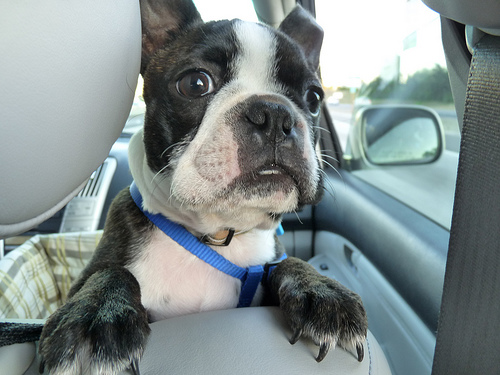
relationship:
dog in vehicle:
[34, 1, 384, 374] [1, 2, 496, 372]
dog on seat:
[34, 1, 384, 374] [1, 312, 387, 375]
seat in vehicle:
[1, 312, 387, 375] [1, 2, 496, 372]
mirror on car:
[344, 104, 452, 172] [1, 2, 496, 372]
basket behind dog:
[1, 230, 112, 329] [34, 1, 384, 374]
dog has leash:
[34, 1, 384, 374] [124, 178, 290, 305]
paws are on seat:
[42, 265, 151, 374] [1, 312, 387, 375]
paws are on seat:
[269, 255, 375, 362] [1, 312, 387, 375]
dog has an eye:
[34, 1, 384, 374] [173, 60, 221, 100]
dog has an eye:
[34, 1, 384, 374] [299, 80, 328, 120]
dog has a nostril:
[34, 1, 384, 374] [247, 111, 272, 130]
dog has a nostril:
[34, 1, 384, 374] [280, 112, 294, 137]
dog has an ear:
[34, 1, 384, 374] [138, 1, 201, 67]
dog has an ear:
[34, 1, 384, 374] [281, 3, 332, 70]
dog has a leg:
[34, 1, 384, 374] [42, 265, 151, 374]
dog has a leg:
[34, 1, 384, 374] [269, 255, 375, 362]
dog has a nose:
[34, 1, 384, 374] [236, 90, 303, 141]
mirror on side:
[344, 104, 452, 172] [293, 4, 499, 298]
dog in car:
[34, 1, 384, 374] [1, 2, 496, 372]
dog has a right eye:
[34, 1, 384, 374] [299, 80, 328, 120]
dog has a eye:
[34, 1, 384, 374] [167, 63, 222, 103]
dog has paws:
[34, 1, 384, 374] [42, 265, 151, 374]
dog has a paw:
[34, 1, 384, 374] [269, 255, 375, 362]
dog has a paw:
[34, 1, 384, 374] [42, 265, 151, 374]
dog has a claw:
[34, 1, 384, 374] [290, 327, 306, 346]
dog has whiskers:
[34, 1, 384, 374] [142, 141, 191, 214]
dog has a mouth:
[34, 1, 384, 374] [242, 153, 310, 213]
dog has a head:
[34, 1, 384, 374] [113, 2, 335, 305]